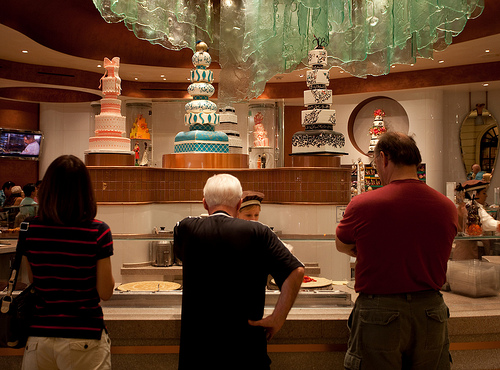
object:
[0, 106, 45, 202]
wall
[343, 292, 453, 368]
pants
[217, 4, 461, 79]
glass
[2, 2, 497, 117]
ceiling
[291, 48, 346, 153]
cake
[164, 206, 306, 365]
t-shirt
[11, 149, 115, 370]
woman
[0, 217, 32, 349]
purse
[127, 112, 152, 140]
doll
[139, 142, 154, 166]
doll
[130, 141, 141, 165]
doll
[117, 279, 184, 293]
desserts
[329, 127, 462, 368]
male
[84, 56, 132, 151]
cake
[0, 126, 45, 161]
television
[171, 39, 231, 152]
cake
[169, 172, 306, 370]
man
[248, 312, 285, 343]
hand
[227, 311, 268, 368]
hip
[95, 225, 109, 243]
stripe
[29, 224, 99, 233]
stripe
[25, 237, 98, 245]
stripe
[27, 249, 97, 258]
stripe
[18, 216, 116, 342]
shirt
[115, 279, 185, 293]
platter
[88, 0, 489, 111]
decor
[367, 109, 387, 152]
cake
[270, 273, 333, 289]
plates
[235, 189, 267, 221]
person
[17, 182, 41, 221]
person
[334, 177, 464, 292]
shirt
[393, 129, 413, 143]
bald spot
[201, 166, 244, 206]
hair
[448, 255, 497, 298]
plate stack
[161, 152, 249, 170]
top shelf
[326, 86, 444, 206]
wall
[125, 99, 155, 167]
case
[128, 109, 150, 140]
cake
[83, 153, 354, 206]
display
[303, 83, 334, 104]
design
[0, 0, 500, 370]
bakery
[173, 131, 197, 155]
blue trim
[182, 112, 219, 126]
purple decorations